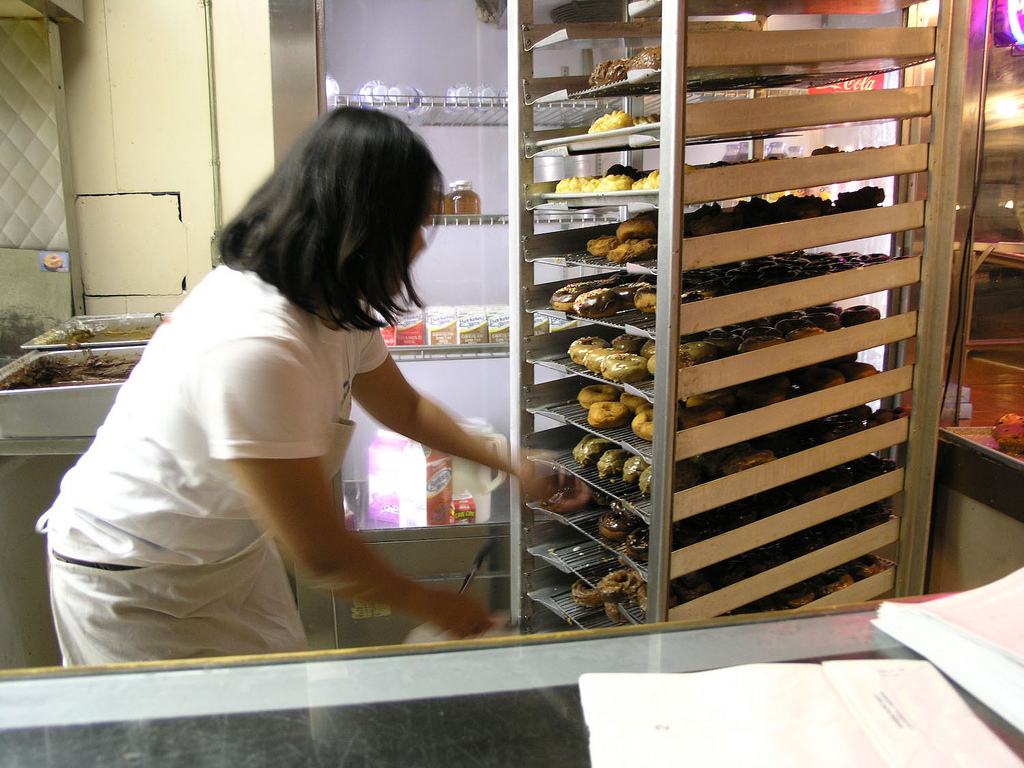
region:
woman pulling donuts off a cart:
[42, 110, 568, 662]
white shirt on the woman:
[45, 287, 393, 566]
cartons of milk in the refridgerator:
[365, 440, 483, 536]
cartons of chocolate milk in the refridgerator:
[425, 300, 568, 349]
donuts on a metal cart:
[531, 28, 904, 630]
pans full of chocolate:
[8, 310, 170, 394]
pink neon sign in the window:
[983, 0, 1022, 52]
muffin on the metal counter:
[988, 408, 1021, 453]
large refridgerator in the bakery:
[266, 0, 906, 662]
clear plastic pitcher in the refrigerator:
[449, 415, 510, 521]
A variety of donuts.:
[504, 5, 925, 607]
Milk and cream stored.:
[365, 397, 512, 537]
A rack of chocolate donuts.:
[525, 201, 899, 332]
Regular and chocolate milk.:
[339, 292, 537, 359]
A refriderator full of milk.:
[260, 2, 688, 626]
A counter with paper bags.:
[5, 617, 1012, 764]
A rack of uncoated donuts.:
[530, 352, 731, 439]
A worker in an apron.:
[13, 83, 599, 650]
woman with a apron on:
[61, 111, 507, 649]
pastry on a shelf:
[522, 221, 677, 457]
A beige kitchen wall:
[68, 23, 245, 319]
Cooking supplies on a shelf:
[327, 50, 509, 109]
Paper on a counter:
[560, 650, 997, 767]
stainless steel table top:
[11, 647, 543, 766]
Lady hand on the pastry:
[367, 350, 598, 510]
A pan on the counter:
[0, 342, 141, 447]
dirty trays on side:
[0, 305, 257, 445]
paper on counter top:
[4, 582, 1020, 766]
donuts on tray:
[498, 5, 970, 639]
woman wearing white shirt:
[38, 98, 570, 694]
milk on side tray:
[324, 408, 527, 538]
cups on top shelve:
[294, 43, 646, 132]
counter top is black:
[0, 592, 1019, 760]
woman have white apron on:
[24, 95, 594, 647]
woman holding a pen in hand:
[27, 98, 598, 636]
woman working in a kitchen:
[40, 114, 571, 666]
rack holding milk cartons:
[354, 335, 535, 367]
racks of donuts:
[499, 13, 921, 636]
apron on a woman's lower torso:
[37, 533, 325, 669]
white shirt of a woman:
[56, 258, 396, 572]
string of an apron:
[25, 496, 67, 536]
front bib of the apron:
[319, 405, 364, 478]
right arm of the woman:
[223, 456, 508, 638]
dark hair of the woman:
[201, 94, 451, 342]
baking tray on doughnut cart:
[644, 33, 924, 85]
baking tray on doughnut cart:
[688, 410, 867, 437]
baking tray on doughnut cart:
[668, 213, 855, 278]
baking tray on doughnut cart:
[693, 258, 908, 322]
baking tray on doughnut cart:
[710, 505, 846, 559]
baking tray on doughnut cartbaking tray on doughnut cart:
[698, 403, 759, 462]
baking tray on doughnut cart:
[706, 6, 896, 64]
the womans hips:
[21, 467, 350, 644]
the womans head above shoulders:
[216, 77, 479, 334]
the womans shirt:
[49, 281, 405, 607]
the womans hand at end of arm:
[495, 436, 560, 507]